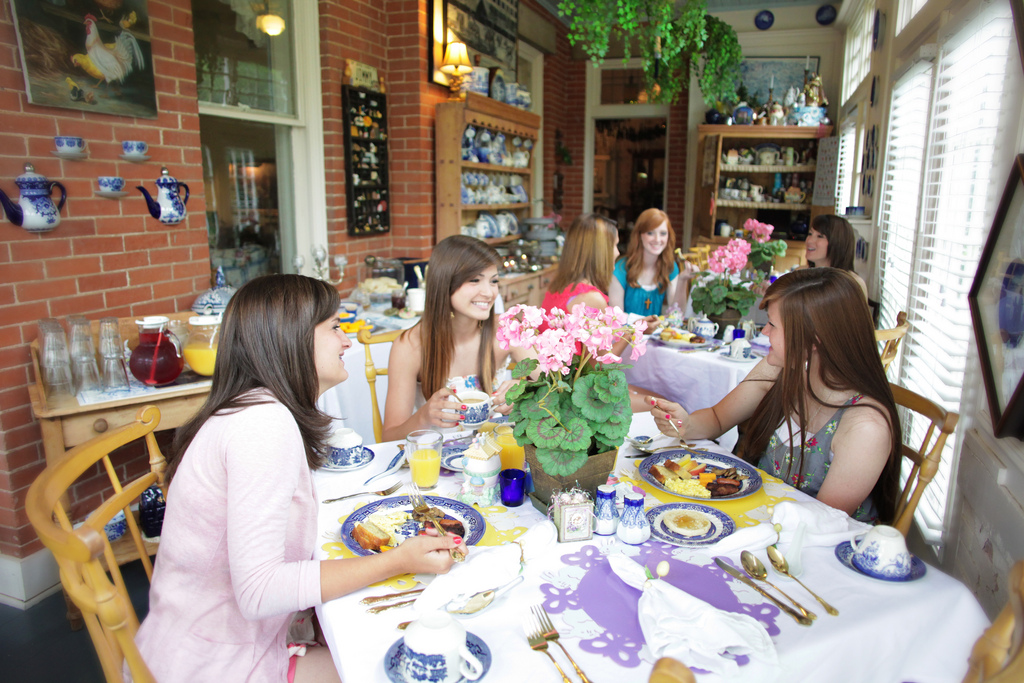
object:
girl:
[128, 274, 460, 683]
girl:
[380, 234, 553, 443]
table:
[306, 408, 1024, 683]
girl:
[644, 267, 902, 525]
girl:
[540, 213, 658, 373]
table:
[597, 292, 769, 456]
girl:
[608, 208, 699, 315]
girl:
[792, 214, 868, 306]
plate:
[638, 449, 762, 500]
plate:
[340, 495, 487, 557]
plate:
[643, 502, 736, 547]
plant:
[495, 303, 646, 521]